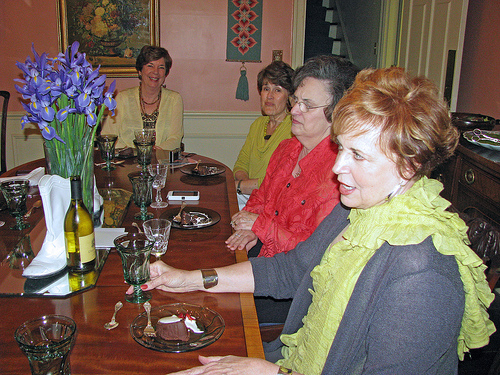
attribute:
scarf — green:
[298, 198, 493, 358]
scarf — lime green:
[274, 173, 498, 373]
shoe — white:
[23, 173, 84, 293]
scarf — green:
[246, 192, 483, 374]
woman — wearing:
[219, 60, 306, 192]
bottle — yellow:
[46, 167, 126, 290]